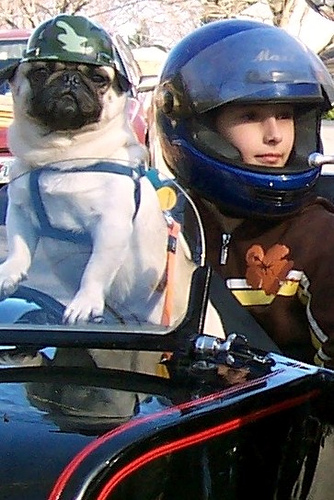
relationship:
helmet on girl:
[155, 16, 332, 209] [154, 20, 334, 385]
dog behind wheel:
[0, 10, 226, 342] [1, 282, 68, 324]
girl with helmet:
[154, 20, 334, 385] [155, 16, 332, 209]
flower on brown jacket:
[244, 241, 293, 293] [171, 189, 333, 371]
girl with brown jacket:
[154, 20, 334, 385] [171, 189, 333, 371]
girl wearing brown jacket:
[175, 26, 332, 373] [171, 189, 333, 371]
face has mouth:
[216, 102, 296, 166] [246, 148, 281, 174]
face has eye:
[201, 89, 310, 173] [244, 108, 263, 129]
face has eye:
[201, 89, 310, 173] [271, 103, 289, 121]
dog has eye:
[1, 10, 169, 324] [86, 70, 103, 82]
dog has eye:
[1, 10, 169, 324] [30, 66, 49, 76]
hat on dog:
[0, 13, 142, 94] [12, 57, 231, 376]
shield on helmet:
[181, 25, 333, 114] [155, 16, 332, 209]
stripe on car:
[32, 362, 284, 498] [0, 167, 334, 500]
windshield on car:
[0, 144, 203, 332] [0, 167, 334, 500]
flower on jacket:
[246, 243, 294, 296] [152, 141, 323, 328]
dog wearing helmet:
[1, 10, 169, 324] [10, 7, 122, 71]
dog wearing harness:
[0, 10, 226, 342] [40, 160, 146, 180]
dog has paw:
[0, 10, 226, 342] [64, 284, 105, 325]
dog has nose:
[0, 10, 226, 342] [60, 69, 81, 89]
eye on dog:
[86, 72, 105, 82] [0, 15, 226, 339]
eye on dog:
[31, 67, 48, 76] [0, 15, 226, 339]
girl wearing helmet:
[154, 20, 334, 385] [225, 70, 251, 110]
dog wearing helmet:
[1, 10, 169, 324] [16, 12, 119, 70]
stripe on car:
[47, 366, 325, 499] [0, 157, 334, 498]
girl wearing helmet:
[154, 20, 334, 385] [155, 16, 332, 209]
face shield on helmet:
[179, 23, 331, 100] [155, 16, 332, 209]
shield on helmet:
[181, 23, 333, 123] [147, 11, 332, 226]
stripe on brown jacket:
[225, 271, 329, 370] [205, 189, 331, 335]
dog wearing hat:
[0, 10, 226, 342] [22, 13, 119, 70]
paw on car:
[63, 293, 105, 325] [0, 167, 334, 500]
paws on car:
[2, 260, 25, 301] [0, 167, 334, 500]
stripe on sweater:
[225, 271, 329, 370] [210, 209, 320, 340]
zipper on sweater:
[214, 230, 233, 264] [173, 182, 332, 368]